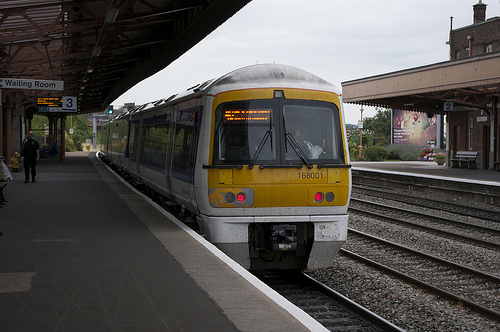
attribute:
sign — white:
[59, 99, 79, 111]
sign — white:
[7, 64, 65, 96]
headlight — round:
[236, 191, 247, 199]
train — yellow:
[91, 58, 376, 282]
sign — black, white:
[0, 78, 64, 90]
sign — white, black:
[474, 115, 488, 120]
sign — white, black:
[62, 96, 74, 106]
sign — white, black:
[35, 95, 62, 105]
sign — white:
[0, 75, 67, 90]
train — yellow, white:
[90, 58, 352, 270]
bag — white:
[304, 138, 332, 168]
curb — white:
[87, 143, 334, 330]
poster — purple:
[386, 105, 441, 149]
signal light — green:
[105, 104, 115, 121]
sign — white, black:
[442, 100, 459, 117]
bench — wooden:
[451, 148, 478, 166]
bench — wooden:
[1, 175, 11, 202]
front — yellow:
[209, 78, 350, 273]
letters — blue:
[2, 78, 59, 88]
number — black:
[437, 92, 460, 115]